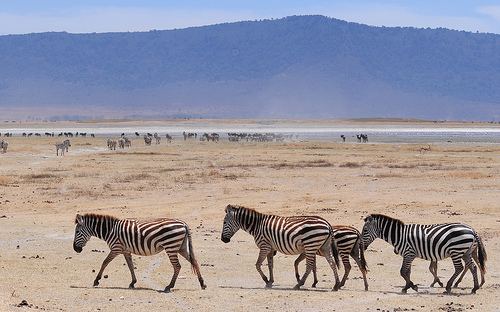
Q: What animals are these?
A: Zebras.